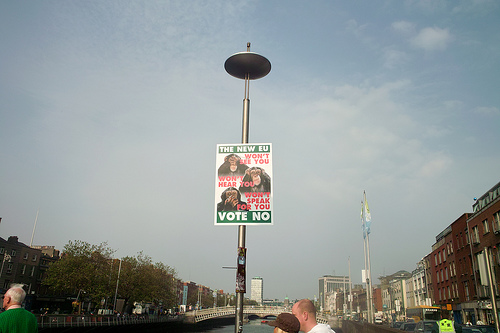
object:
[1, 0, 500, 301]
sky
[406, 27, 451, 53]
cloud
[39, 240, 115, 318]
tree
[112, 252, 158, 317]
tree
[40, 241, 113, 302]
leaves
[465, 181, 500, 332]
building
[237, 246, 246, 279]
light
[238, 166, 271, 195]
monkey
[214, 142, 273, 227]
poster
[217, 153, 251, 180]
monkey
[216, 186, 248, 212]
monkey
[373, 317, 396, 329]
street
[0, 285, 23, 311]
head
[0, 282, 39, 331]
man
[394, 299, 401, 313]
sign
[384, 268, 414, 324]
building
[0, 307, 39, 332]
sweater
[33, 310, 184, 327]
street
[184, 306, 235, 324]
bridge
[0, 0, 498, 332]
scene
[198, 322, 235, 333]
river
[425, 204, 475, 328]
building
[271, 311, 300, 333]
woman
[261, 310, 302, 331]
hat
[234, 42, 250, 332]
pole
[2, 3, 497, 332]
city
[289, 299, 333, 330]
man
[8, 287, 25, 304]
hair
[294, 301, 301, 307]
hairline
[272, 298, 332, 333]
couple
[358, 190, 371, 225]
flag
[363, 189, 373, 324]
flagpole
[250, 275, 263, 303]
skyscraper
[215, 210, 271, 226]
vote no